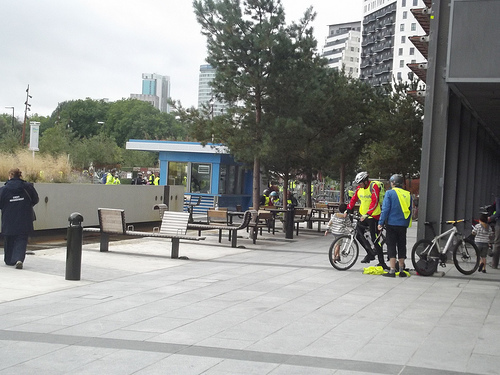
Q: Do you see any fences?
A: No, there are no fences.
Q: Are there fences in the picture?
A: No, there are no fences.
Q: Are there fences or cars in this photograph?
A: No, there are no fences or cars.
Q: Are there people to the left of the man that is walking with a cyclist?
A: Yes, there is a person to the left of the man.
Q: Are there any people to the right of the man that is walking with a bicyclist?
A: No, the person is to the left of the man.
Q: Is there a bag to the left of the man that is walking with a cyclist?
A: No, there is a person to the left of the man.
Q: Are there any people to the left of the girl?
A: Yes, there is a person to the left of the girl.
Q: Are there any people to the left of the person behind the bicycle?
A: Yes, there is a person to the left of the girl.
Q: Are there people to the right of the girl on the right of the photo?
A: No, the person is to the left of the girl.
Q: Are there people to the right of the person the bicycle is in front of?
A: No, the person is to the left of the girl.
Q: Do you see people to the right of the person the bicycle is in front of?
A: No, the person is to the left of the girl.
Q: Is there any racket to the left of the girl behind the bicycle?
A: No, there is a person to the left of the girl.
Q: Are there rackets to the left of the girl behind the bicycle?
A: No, there is a person to the left of the girl.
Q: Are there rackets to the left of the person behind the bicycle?
A: No, there is a person to the left of the girl.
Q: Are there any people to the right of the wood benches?
A: Yes, there is a person to the right of the benches.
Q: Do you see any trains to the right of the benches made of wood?
A: No, there is a person to the right of the benches.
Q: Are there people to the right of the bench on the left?
A: Yes, there is a person to the right of the bench.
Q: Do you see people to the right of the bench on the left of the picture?
A: Yes, there is a person to the right of the bench.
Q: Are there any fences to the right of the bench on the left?
A: No, there is a person to the right of the bench.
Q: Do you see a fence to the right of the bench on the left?
A: No, there is a person to the right of the bench.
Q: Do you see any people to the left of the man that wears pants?
A: Yes, there is a person to the left of the man.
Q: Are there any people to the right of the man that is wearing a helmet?
A: No, the person is to the left of the man.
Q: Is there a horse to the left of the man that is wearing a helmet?
A: No, there is a person to the left of the man.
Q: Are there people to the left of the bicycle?
A: Yes, there is a person to the left of the bicycle.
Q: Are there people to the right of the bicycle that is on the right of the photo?
A: No, the person is to the left of the bicycle.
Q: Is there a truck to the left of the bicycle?
A: No, there is a person to the left of the bicycle.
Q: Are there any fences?
A: No, there are no fences.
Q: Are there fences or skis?
A: No, there are no fences or skis.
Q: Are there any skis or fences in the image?
A: No, there are no fences or skis.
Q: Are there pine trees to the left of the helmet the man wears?
A: Yes, there is a pine tree to the left of the helmet.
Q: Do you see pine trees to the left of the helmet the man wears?
A: Yes, there is a pine tree to the left of the helmet.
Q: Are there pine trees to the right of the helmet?
A: No, the pine tree is to the left of the helmet.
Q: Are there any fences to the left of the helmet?
A: No, there is a pine tree to the left of the helmet.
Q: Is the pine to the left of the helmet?
A: Yes, the pine is to the left of the helmet.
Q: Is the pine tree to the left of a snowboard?
A: No, the pine tree is to the left of the helmet.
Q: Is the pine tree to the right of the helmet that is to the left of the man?
A: No, the pine tree is to the left of the helmet.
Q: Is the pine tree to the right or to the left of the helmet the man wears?
A: The pine tree is to the left of the helmet.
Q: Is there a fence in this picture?
A: No, there are no fences.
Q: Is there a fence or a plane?
A: No, there are no fences or airplanes.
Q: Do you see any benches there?
A: Yes, there is a bench.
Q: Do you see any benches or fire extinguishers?
A: Yes, there is a bench.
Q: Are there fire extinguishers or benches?
A: Yes, there is a bench.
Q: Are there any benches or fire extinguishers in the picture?
A: Yes, there is a bench.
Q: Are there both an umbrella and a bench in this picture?
A: No, there is a bench but no umbrellas.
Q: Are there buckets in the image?
A: No, there are no buckets.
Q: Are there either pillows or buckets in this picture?
A: No, there are no buckets or pillows.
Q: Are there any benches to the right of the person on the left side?
A: Yes, there is a bench to the right of the person.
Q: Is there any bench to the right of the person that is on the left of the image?
A: Yes, there is a bench to the right of the person.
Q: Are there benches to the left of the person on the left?
A: No, the bench is to the right of the person.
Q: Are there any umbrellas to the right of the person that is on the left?
A: No, there is a bench to the right of the person.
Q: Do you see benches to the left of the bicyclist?
A: Yes, there is a bench to the left of the bicyclist.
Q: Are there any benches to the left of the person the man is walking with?
A: Yes, there is a bench to the left of the bicyclist.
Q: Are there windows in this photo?
A: Yes, there is a window.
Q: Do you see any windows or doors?
A: Yes, there is a window.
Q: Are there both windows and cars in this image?
A: No, there is a window but no cars.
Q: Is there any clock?
A: No, there are no clocks.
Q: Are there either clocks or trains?
A: No, there are no clocks or trains.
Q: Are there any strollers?
A: No, there are no strollers.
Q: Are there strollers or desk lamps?
A: No, there are no strollers or desk lamps.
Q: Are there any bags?
A: No, there are no bags.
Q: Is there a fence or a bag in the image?
A: No, there are no bags or fences.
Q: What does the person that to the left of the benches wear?
A: The person wears a jacket.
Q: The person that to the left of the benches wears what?
A: The person wears a jacket.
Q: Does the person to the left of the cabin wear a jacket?
A: Yes, the person wears a jacket.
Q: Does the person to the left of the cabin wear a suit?
A: No, the person wears a jacket.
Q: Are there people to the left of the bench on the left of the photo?
A: Yes, there is a person to the left of the bench.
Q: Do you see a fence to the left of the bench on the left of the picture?
A: No, there is a person to the left of the bench.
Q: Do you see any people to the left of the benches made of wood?
A: Yes, there is a person to the left of the benches.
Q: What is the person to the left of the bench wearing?
A: The person is wearing a jacket.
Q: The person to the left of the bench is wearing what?
A: The person is wearing a jacket.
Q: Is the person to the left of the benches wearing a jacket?
A: Yes, the person is wearing a jacket.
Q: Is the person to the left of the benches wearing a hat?
A: No, the person is wearing a jacket.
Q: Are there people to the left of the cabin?
A: Yes, there is a person to the left of the cabin.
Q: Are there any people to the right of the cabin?
A: No, the person is to the left of the cabin.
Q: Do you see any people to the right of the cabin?
A: No, the person is to the left of the cabin.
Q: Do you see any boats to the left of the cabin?
A: No, there is a person to the left of the cabin.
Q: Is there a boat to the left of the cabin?
A: No, there is a person to the left of the cabin.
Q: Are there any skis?
A: No, there are no skis.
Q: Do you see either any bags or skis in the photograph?
A: No, there are no skis or bags.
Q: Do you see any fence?
A: No, there are no fences.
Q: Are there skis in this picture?
A: No, there are no skis.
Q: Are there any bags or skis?
A: No, there are no skis or bags.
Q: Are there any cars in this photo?
A: No, there are no cars.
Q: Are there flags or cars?
A: No, there are no cars or flags.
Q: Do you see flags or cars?
A: No, there are no cars or flags.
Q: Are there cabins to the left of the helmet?
A: Yes, there is a cabin to the left of the helmet.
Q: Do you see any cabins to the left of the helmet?
A: Yes, there is a cabin to the left of the helmet.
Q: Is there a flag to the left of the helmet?
A: No, there is a cabin to the left of the helmet.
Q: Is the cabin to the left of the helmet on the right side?
A: Yes, the cabin is to the left of the helmet.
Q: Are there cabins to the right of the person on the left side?
A: Yes, there is a cabin to the right of the person.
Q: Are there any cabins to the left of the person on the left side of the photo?
A: No, the cabin is to the right of the person.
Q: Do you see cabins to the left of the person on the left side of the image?
A: No, the cabin is to the right of the person.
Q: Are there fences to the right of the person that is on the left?
A: No, there is a cabin to the right of the person.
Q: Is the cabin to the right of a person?
A: Yes, the cabin is to the right of a person.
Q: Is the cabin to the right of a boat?
A: No, the cabin is to the right of a person.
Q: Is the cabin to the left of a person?
A: No, the cabin is to the right of a person.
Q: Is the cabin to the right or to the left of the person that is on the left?
A: The cabin is to the right of the person.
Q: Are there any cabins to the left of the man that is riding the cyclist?
A: Yes, there is a cabin to the left of the man.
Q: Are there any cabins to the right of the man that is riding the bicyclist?
A: No, the cabin is to the left of the man.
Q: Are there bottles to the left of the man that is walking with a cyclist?
A: No, there is a cabin to the left of the man.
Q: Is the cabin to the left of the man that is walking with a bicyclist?
A: Yes, the cabin is to the left of the man.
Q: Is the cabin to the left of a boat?
A: No, the cabin is to the left of the man.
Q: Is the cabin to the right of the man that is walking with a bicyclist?
A: No, the cabin is to the left of the man.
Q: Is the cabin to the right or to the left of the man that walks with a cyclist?
A: The cabin is to the left of the man.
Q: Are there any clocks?
A: No, there are no clocks.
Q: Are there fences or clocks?
A: No, there are no clocks or fences.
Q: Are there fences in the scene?
A: No, there are no fences.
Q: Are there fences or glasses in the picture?
A: No, there are no fences or glasses.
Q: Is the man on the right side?
A: Yes, the man is on the right of the image.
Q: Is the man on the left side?
A: No, the man is on the right of the image.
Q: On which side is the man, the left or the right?
A: The man is on the right of the image.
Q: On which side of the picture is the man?
A: The man is on the right of the image.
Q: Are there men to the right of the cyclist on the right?
A: Yes, there is a man to the right of the bicyclist.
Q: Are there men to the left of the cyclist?
A: No, the man is to the right of the cyclist.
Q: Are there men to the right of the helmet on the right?
A: Yes, there is a man to the right of the helmet.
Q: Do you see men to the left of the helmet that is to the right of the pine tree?
A: No, the man is to the right of the helmet.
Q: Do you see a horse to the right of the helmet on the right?
A: No, there is a man to the right of the helmet.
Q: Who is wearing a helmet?
A: The man is wearing a helmet.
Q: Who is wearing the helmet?
A: The man is wearing a helmet.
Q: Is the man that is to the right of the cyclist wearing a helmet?
A: Yes, the man is wearing a helmet.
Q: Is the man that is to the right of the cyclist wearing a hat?
A: No, the man is wearing a helmet.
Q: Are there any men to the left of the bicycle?
A: Yes, there is a man to the left of the bicycle.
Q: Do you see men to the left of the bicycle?
A: Yes, there is a man to the left of the bicycle.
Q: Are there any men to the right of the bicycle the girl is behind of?
A: No, the man is to the left of the bicycle.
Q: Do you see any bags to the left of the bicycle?
A: No, there is a man to the left of the bicycle.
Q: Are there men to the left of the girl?
A: Yes, there is a man to the left of the girl.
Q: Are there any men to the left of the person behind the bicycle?
A: Yes, there is a man to the left of the girl.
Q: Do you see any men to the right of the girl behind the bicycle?
A: No, the man is to the left of the girl.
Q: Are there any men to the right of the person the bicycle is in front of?
A: No, the man is to the left of the girl.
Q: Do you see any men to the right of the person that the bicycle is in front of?
A: No, the man is to the left of the girl.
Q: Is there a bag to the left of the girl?
A: No, there is a man to the left of the girl.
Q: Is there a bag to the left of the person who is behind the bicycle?
A: No, there is a man to the left of the girl.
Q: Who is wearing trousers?
A: The man is wearing trousers.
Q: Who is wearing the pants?
A: The man is wearing trousers.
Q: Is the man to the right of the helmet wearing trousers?
A: Yes, the man is wearing trousers.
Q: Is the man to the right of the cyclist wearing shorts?
A: No, the man is wearing trousers.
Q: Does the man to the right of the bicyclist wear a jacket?
A: Yes, the man wears a jacket.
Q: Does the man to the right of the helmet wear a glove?
A: No, the man wears a jacket.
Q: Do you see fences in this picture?
A: No, there are no fences.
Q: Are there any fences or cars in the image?
A: No, there are no fences or cars.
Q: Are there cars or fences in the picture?
A: No, there are no fences or cars.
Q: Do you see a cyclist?
A: Yes, there is a cyclist.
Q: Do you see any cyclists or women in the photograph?
A: Yes, there is a cyclist.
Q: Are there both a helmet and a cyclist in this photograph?
A: Yes, there are both a cyclist and a helmet.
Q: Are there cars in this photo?
A: No, there are no cars.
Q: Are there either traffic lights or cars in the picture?
A: No, there are no cars or traffic lights.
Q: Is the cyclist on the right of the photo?
A: Yes, the cyclist is on the right of the image.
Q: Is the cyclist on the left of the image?
A: No, the cyclist is on the right of the image.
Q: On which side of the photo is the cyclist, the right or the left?
A: The cyclist is on the right of the image.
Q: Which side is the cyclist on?
A: The cyclist is on the right of the image.